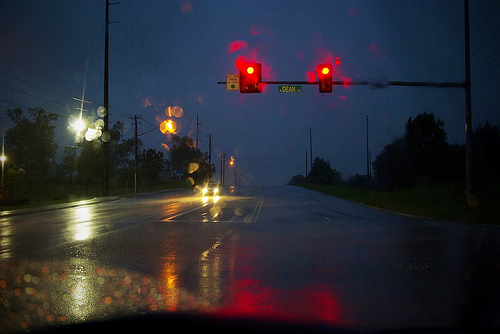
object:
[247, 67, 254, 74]
light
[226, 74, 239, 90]
sign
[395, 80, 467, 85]
pole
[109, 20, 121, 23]
lines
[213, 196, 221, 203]
headlights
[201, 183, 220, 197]
car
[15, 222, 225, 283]
pavement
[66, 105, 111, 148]
lamp post\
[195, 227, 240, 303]
road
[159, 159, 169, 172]
post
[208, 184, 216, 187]
window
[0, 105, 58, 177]
trees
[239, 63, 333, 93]
traffic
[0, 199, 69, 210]
grass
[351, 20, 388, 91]
sky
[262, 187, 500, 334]
street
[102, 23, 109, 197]
poles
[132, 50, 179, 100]
water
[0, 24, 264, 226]
windshield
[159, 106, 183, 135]
streetlight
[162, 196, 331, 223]
roadway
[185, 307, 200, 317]
wiper